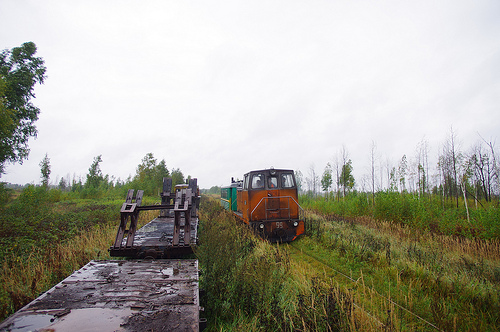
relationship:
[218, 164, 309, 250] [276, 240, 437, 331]
train on tracks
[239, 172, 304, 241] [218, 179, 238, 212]
train engine pulling train cars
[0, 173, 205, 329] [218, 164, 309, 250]
flatbed rail car by train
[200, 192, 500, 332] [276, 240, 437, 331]
grass by tracks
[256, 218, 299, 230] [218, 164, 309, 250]
headlights on train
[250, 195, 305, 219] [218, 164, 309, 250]
railing on train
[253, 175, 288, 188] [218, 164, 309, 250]
engineer on train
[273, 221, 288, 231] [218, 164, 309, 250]
95 on train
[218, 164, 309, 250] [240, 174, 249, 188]
train has windows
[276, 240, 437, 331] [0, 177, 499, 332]
tracks in field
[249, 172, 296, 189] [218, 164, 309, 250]
windshield on train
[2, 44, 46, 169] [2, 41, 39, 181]
leaves on tree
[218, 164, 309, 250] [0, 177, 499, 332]
train in field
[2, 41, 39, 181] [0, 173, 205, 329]
tree next to flatbed rail car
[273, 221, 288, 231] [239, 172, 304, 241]
95 on train engine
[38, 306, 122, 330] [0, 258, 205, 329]
puddle on section